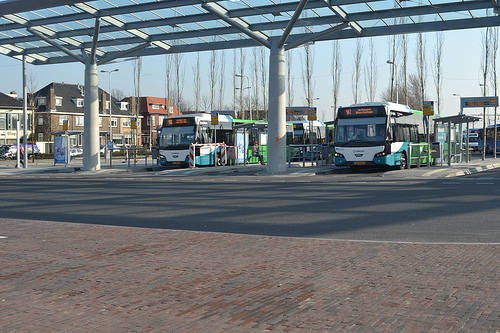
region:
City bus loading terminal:
[4, 1, 499, 182]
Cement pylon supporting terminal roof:
[262, 37, 291, 176]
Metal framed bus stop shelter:
[434, 112, 478, 167]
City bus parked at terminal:
[326, 100, 455, 172]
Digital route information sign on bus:
[340, 105, 377, 117]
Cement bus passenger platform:
[387, 153, 498, 178]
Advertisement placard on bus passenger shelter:
[51, 133, 71, 166]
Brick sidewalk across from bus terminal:
[2, 213, 498, 330]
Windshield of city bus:
[331, 123, 388, 144]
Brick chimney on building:
[46, 86, 59, 111]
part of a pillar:
[266, 149, 285, 177]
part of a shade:
[303, 192, 347, 253]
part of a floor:
[282, 243, 309, 270]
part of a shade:
[330, 182, 362, 222]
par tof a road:
[273, 215, 291, 235]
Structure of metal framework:
[2, 0, 496, 182]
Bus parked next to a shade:
[327, 100, 481, 172]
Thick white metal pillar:
[80, 64, 104, 172]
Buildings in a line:
[0, 78, 195, 178]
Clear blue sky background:
[1, 28, 497, 127]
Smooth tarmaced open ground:
[2, 180, 496, 328]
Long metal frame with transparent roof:
[1, 1, 498, 65]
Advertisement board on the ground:
[49, 132, 71, 167]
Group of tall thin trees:
[22, 0, 497, 162]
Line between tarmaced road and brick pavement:
[1, 208, 498, 251]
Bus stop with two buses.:
[2, 4, 497, 188]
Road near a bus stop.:
[4, 175, 494, 247]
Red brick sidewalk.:
[2, 217, 495, 328]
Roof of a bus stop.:
[1, 0, 498, 66]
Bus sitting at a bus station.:
[327, 100, 434, 171]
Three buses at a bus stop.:
[141, 99, 443, 172]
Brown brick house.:
[32, 81, 142, 156]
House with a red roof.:
[125, 96, 179, 147]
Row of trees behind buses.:
[122, 28, 494, 156]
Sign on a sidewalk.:
[49, 132, 75, 169]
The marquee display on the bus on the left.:
[166, 118, 189, 123]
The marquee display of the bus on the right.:
[340, 108, 382, 116]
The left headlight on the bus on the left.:
[159, 155, 162, 158]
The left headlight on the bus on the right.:
[332, 151, 342, 158]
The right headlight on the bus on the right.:
[377, 148, 385, 156]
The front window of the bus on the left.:
[156, 125, 195, 150]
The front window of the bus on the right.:
[336, 118, 383, 143]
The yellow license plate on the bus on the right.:
[354, 160, 367, 165]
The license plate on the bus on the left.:
[168, 161, 183, 166]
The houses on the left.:
[1, 83, 186, 163]